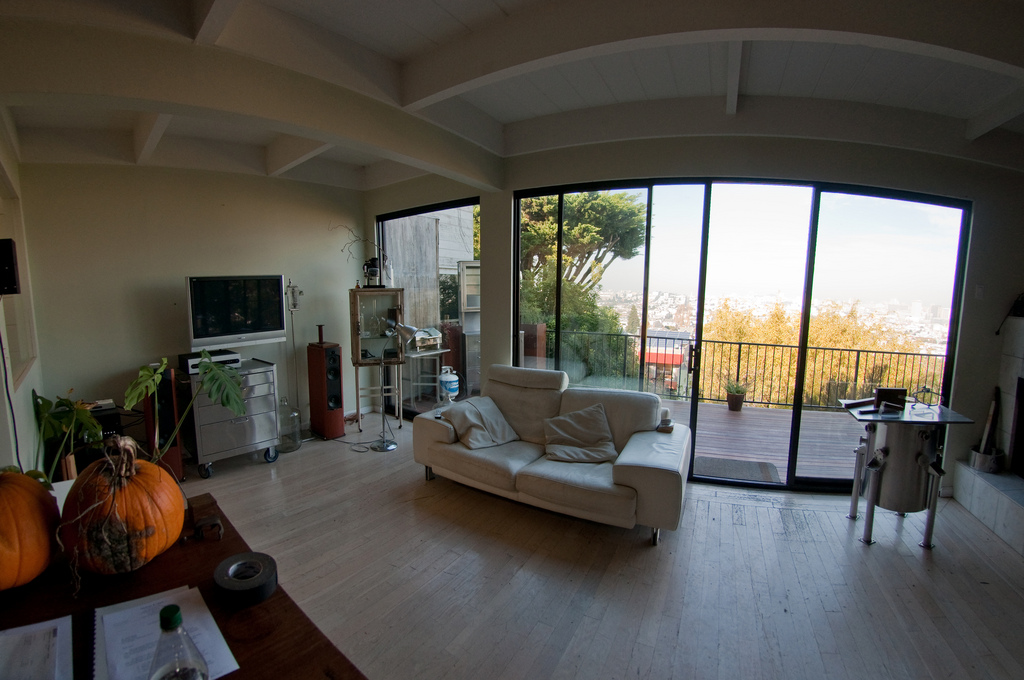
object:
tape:
[204, 547, 279, 597]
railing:
[539, 320, 944, 419]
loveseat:
[409, 361, 694, 545]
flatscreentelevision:
[178, 269, 292, 350]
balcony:
[517, 328, 958, 485]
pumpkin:
[50, 429, 190, 579]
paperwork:
[5, 582, 232, 669]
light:
[219, 416, 1013, 644]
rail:
[539, 325, 945, 414]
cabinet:
[187, 358, 283, 471]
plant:
[718, 383, 754, 412]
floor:
[685, 393, 914, 474]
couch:
[416, 364, 692, 535]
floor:
[253, 410, 1023, 677]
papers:
[99, 587, 249, 677]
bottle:
[134, 603, 222, 677]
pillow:
[441, 394, 518, 450]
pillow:
[543, 401, 616, 464]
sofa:
[404, 375, 689, 533]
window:
[796, 185, 938, 484]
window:
[698, 213, 822, 483]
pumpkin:
[0, 458, 59, 593]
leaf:
[202, 359, 256, 410]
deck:
[523, 325, 952, 481]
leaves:
[118, 352, 173, 412]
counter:
[2, 488, 322, 675]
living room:
[16, 35, 994, 675]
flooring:
[202, 404, 1013, 675]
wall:
[27, 169, 407, 478]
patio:
[488, 325, 953, 482]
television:
[180, 266, 295, 354]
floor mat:
[678, 448, 782, 492]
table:
[5, 492, 351, 675]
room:
[2, 46, 1021, 671]